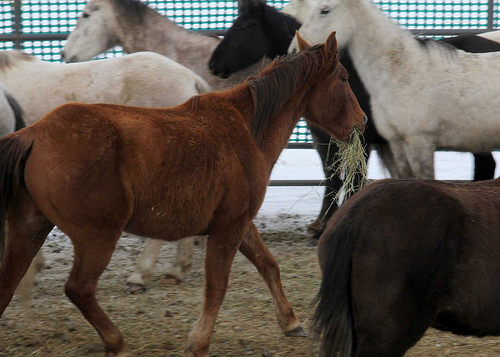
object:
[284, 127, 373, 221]
grass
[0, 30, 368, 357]
horse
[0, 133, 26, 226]
tail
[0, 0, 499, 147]
fencing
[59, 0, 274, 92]
horse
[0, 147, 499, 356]
ground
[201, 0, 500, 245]
horse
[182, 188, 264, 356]
right leg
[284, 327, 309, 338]
hoof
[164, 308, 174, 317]
rocks